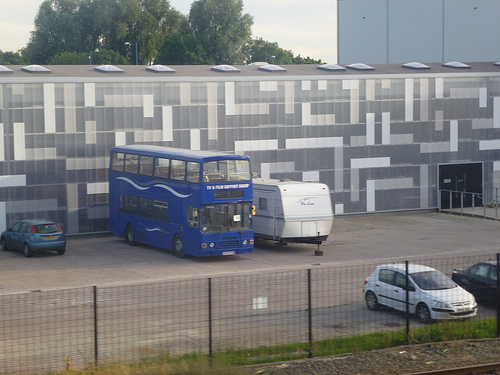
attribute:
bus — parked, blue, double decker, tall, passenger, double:
[128, 112, 254, 262]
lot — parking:
[75, 216, 373, 321]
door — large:
[416, 153, 469, 204]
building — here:
[299, 38, 489, 185]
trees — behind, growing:
[49, 4, 214, 76]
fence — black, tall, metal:
[215, 282, 276, 332]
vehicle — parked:
[371, 255, 498, 351]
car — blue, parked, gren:
[17, 209, 115, 284]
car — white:
[407, 259, 499, 332]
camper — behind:
[265, 179, 331, 237]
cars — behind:
[406, 253, 496, 318]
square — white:
[71, 83, 119, 110]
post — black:
[188, 263, 249, 362]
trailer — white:
[272, 184, 358, 249]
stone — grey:
[255, 87, 375, 159]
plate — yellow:
[19, 236, 78, 253]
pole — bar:
[194, 274, 249, 353]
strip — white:
[147, 100, 187, 145]